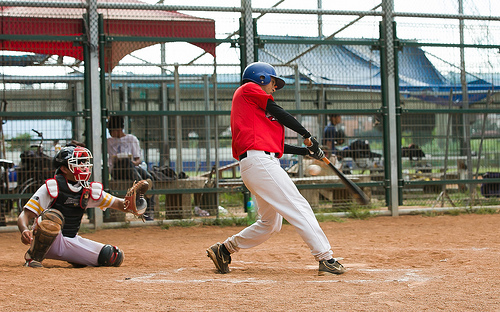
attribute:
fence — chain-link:
[316, 45, 369, 123]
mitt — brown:
[122, 177, 150, 213]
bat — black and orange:
[305, 142, 374, 205]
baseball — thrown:
[306, 162, 321, 174]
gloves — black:
[299, 129, 321, 164]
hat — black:
[230, 55, 317, 106]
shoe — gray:
[204, 234, 242, 276]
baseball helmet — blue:
[240, 60, 287, 87]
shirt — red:
[194, 61, 318, 163]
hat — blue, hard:
[244, 62, 286, 93]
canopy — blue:
[237, 35, 493, 103]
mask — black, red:
[68, 144, 92, 188]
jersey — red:
[227, 82, 288, 158]